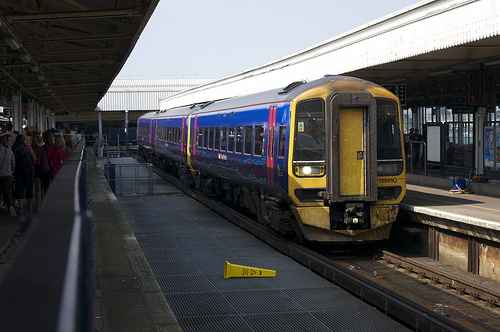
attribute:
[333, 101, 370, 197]
door — yellow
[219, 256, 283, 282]
cone — yellow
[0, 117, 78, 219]
people — several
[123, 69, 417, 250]
train — long, blue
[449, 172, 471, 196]
item — blue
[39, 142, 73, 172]
jacket — red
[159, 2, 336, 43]
sky — blue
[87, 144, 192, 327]
pavement — wet